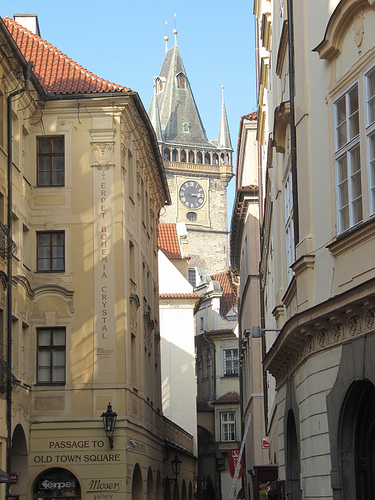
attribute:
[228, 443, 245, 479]
banner — red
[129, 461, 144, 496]
arch — rounded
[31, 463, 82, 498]
arch — rounded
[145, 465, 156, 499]
arch — rounded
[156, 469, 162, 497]
arch — rounded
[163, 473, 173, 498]
arch — rounded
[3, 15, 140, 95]
roof — terracotta, stone, red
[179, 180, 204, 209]
face — black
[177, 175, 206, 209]
numbers — white